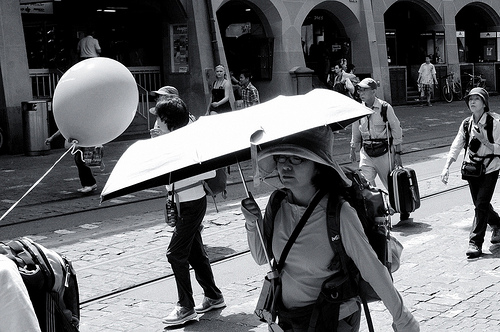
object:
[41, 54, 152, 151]
balloon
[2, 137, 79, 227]
string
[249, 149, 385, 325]
lady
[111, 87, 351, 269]
umbrella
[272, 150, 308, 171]
glasses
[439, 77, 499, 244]
woman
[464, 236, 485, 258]
shoe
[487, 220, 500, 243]
shoe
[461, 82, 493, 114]
hat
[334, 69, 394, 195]
man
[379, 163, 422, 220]
suitcase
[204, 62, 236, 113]
girl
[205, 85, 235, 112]
dress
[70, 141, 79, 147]
knot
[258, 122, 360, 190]
hat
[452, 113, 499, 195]
shirt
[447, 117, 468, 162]
sleeves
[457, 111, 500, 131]
backpack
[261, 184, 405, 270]
backpack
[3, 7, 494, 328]
picture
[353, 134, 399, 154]
bellypack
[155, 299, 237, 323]
sneakers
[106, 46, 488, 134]
people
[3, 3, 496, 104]
building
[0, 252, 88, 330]
person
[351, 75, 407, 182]
person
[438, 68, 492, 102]
bikes